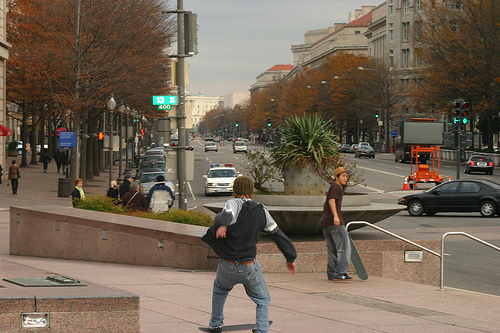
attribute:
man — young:
[320, 164, 352, 282]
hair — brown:
[233, 174, 250, 195]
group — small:
[76, 153, 201, 233]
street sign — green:
[147, 92, 185, 110]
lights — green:
[205, 110, 483, 138]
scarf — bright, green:
[74, 185, 84, 203]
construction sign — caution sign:
[392, 116, 456, 192]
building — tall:
[385, 3, 427, 68]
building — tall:
[367, 4, 389, 59]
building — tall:
[301, 11, 375, 66]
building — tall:
[294, 28, 312, 61]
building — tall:
[246, 62, 288, 89]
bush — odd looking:
[270, 102, 362, 194]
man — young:
[319, 165, 359, 283]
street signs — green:
[148, 93, 183, 110]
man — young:
[317, 159, 374, 302]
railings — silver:
[340, 216, 496, 296]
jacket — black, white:
[143, 180, 174, 214]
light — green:
[461, 117, 469, 124]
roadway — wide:
[194, 137, 426, 192]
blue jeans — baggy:
[202, 247, 260, 312]